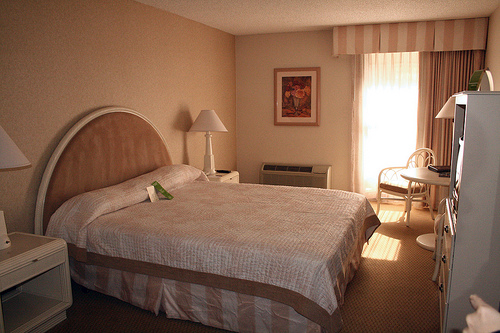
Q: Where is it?
A: This is at the bedroom.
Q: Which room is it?
A: It is a bedroom.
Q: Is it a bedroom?
A: Yes, it is a bedroom.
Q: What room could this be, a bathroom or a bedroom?
A: It is a bedroom.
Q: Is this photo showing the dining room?
A: No, the picture is showing the bedroom.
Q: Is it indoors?
A: Yes, it is indoors.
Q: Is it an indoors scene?
A: Yes, it is indoors.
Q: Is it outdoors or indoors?
A: It is indoors.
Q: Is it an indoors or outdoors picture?
A: It is indoors.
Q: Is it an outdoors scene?
A: No, it is indoors.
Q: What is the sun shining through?
A: The sun is shining through the window.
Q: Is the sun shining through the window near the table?
A: Yes, the sun is shining through the window.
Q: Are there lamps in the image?
A: Yes, there is a lamp.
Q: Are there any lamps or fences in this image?
A: Yes, there is a lamp.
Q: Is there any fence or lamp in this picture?
A: Yes, there is a lamp.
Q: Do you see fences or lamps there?
A: Yes, there is a lamp.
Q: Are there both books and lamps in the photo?
A: No, there is a lamp but no books.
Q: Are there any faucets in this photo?
A: No, there are no faucets.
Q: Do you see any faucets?
A: No, there are no faucets.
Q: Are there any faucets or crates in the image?
A: No, there are no faucets or crates.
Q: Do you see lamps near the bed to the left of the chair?
A: Yes, there is a lamp near the bed.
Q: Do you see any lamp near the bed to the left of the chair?
A: Yes, there is a lamp near the bed.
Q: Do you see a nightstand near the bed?
A: No, there is a lamp near the bed.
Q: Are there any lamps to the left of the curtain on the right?
A: Yes, there is a lamp to the left of the curtain.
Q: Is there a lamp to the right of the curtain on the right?
A: No, the lamp is to the left of the curtain.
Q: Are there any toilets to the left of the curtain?
A: No, there is a lamp to the left of the curtain.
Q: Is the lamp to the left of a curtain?
A: Yes, the lamp is to the left of a curtain.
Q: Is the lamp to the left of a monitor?
A: No, the lamp is to the left of a curtain.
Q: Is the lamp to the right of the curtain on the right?
A: No, the lamp is to the left of the curtain.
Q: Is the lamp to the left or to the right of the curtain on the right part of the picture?
A: The lamp is to the left of the curtain.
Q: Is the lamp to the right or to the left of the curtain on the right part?
A: The lamp is to the left of the curtain.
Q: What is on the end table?
A: The lamp is on the end table.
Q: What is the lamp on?
A: The lamp is on the end table.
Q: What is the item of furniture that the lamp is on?
A: The piece of furniture is an end table.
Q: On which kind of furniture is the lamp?
A: The lamp is on the end table.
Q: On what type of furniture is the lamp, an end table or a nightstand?
A: The lamp is on an end table.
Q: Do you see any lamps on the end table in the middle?
A: Yes, there is a lamp on the end table.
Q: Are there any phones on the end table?
A: No, there is a lamp on the end table.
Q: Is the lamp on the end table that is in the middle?
A: Yes, the lamp is on the end table.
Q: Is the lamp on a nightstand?
A: No, the lamp is on the end table.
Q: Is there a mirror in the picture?
A: No, there are no mirrors.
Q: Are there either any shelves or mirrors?
A: No, there are no mirrors or shelves.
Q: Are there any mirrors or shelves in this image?
A: No, there are no mirrors or shelves.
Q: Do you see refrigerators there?
A: No, there are no refrigerators.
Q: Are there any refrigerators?
A: No, there are no refrigerators.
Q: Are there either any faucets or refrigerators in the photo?
A: No, there are no refrigerators or faucets.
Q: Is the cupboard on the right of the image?
A: Yes, the cupboard is on the right of the image.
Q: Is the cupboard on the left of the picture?
A: No, the cupboard is on the right of the image.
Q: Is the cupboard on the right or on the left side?
A: The cupboard is on the right of the image.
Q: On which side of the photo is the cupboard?
A: The cupboard is on the right of the image.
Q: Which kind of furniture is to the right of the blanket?
A: The piece of furniture is a cupboard.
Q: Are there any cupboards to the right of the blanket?
A: Yes, there is a cupboard to the right of the blanket.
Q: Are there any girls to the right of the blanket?
A: No, there is a cupboard to the right of the blanket.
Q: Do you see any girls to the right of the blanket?
A: No, there is a cupboard to the right of the blanket.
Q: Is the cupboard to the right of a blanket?
A: Yes, the cupboard is to the right of a blanket.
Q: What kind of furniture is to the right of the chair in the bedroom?
A: The piece of furniture is a cupboard.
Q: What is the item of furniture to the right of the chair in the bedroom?
A: The piece of furniture is a cupboard.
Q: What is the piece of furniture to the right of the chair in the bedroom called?
A: The piece of furniture is a cupboard.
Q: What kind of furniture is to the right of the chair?
A: The piece of furniture is a cupboard.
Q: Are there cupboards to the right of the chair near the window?
A: Yes, there is a cupboard to the right of the chair.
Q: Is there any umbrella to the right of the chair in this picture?
A: No, there is a cupboard to the right of the chair.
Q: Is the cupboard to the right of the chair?
A: Yes, the cupboard is to the right of the chair.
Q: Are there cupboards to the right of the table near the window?
A: Yes, there is a cupboard to the right of the table.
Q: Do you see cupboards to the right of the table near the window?
A: Yes, there is a cupboard to the right of the table.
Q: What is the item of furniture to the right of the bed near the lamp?
A: The piece of furniture is a cupboard.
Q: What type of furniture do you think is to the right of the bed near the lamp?
A: The piece of furniture is a cupboard.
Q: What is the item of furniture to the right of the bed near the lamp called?
A: The piece of furniture is a cupboard.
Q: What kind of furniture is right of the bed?
A: The piece of furniture is a cupboard.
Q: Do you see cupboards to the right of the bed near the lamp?
A: Yes, there is a cupboard to the right of the bed.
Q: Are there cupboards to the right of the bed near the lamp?
A: Yes, there is a cupboard to the right of the bed.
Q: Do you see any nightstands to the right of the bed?
A: No, there is a cupboard to the right of the bed.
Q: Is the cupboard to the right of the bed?
A: Yes, the cupboard is to the right of the bed.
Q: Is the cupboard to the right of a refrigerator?
A: No, the cupboard is to the right of the bed.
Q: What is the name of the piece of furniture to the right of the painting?
A: The piece of furniture is a cupboard.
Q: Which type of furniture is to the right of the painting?
A: The piece of furniture is a cupboard.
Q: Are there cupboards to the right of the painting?
A: Yes, there is a cupboard to the right of the painting.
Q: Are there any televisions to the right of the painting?
A: No, there is a cupboard to the right of the painting.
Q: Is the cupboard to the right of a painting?
A: Yes, the cupboard is to the right of a painting.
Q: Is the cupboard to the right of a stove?
A: No, the cupboard is to the right of a painting.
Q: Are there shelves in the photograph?
A: No, there are no shelves.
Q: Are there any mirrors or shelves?
A: No, there are no shelves or mirrors.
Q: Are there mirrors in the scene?
A: No, there are no mirrors.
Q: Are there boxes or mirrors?
A: No, there are no mirrors or boxes.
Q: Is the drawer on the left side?
A: No, the drawer is on the right of the image.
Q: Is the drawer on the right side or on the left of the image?
A: The drawer is on the right of the image.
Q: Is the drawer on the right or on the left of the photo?
A: The drawer is on the right of the image.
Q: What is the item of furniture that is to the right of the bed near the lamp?
A: The piece of furniture is a drawer.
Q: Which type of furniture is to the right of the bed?
A: The piece of furniture is a drawer.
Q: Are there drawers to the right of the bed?
A: Yes, there is a drawer to the right of the bed.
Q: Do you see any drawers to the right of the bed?
A: Yes, there is a drawer to the right of the bed.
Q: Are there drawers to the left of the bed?
A: No, the drawer is to the right of the bed.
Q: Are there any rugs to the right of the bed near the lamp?
A: No, there is a drawer to the right of the bed.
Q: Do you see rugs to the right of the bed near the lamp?
A: No, there is a drawer to the right of the bed.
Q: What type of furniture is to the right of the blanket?
A: The piece of furniture is a drawer.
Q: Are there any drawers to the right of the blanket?
A: Yes, there is a drawer to the right of the blanket.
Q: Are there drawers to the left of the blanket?
A: No, the drawer is to the right of the blanket.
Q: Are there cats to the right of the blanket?
A: No, there is a drawer to the right of the blanket.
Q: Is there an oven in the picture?
A: No, there are no ovens.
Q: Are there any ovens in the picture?
A: No, there are no ovens.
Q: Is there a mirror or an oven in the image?
A: No, there are no ovens or mirrors.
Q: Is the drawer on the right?
A: Yes, the drawer is on the right of the image.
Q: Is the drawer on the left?
A: No, the drawer is on the right of the image.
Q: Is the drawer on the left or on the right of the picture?
A: The drawer is on the right of the image.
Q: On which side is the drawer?
A: The drawer is on the right of the image.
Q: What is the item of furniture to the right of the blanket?
A: The piece of furniture is a drawer.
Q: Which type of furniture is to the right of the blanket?
A: The piece of furniture is a drawer.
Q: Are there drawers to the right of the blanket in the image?
A: Yes, there is a drawer to the right of the blanket.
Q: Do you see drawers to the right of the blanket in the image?
A: Yes, there is a drawer to the right of the blanket.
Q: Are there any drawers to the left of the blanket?
A: No, the drawer is to the right of the blanket.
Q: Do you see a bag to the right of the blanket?
A: No, there is a drawer to the right of the blanket.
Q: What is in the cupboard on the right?
A: The drawer is in the cupboard.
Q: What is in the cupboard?
A: The drawer is in the cupboard.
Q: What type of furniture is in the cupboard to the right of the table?
A: The piece of furniture is a drawer.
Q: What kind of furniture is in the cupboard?
A: The piece of furniture is a drawer.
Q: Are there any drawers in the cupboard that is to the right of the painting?
A: Yes, there is a drawer in the cupboard.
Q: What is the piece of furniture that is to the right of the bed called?
A: The piece of furniture is a drawer.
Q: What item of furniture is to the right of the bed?
A: The piece of furniture is a drawer.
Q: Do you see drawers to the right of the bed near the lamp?
A: Yes, there is a drawer to the right of the bed.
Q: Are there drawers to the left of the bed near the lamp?
A: No, the drawer is to the right of the bed.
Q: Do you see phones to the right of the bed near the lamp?
A: No, there is a drawer to the right of the bed.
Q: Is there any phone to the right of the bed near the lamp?
A: No, there is a drawer to the right of the bed.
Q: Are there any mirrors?
A: No, there are no mirrors.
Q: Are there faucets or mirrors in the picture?
A: No, there are no mirrors or faucets.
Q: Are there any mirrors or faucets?
A: No, there are no mirrors or faucets.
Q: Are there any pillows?
A: Yes, there is a pillow.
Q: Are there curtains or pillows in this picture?
A: Yes, there is a pillow.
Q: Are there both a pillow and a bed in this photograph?
A: Yes, there are both a pillow and a bed.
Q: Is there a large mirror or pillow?
A: Yes, there is a large pillow.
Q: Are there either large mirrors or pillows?
A: Yes, there is a large pillow.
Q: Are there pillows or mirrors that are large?
A: Yes, the pillow is large.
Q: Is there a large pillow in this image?
A: Yes, there is a large pillow.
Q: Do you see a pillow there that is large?
A: Yes, there is a pillow that is large.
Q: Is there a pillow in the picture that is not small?
A: Yes, there is a large pillow.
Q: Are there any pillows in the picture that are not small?
A: Yes, there is a large pillow.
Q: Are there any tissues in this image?
A: No, there are no tissues.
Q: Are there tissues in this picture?
A: No, there are no tissues.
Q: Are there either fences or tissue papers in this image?
A: No, there are no tissue papers or fences.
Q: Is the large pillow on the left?
A: Yes, the pillow is on the left of the image.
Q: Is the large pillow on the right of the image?
A: No, the pillow is on the left of the image.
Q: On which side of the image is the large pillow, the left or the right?
A: The pillow is on the left of the image.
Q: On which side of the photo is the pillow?
A: The pillow is on the left of the image.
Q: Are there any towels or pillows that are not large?
A: No, there is a pillow but it is large.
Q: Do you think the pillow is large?
A: Yes, the pillow is large.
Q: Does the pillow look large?
A: Yes, the pillow is large.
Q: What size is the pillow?
A: The pillow is large.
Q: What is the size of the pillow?
A: The pillow is large.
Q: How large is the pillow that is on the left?
A: The pillow is large.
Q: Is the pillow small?
A: No, the pillow is large.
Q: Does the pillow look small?
A: No, the pillow is large.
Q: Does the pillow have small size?
A: No, the pillow is large.